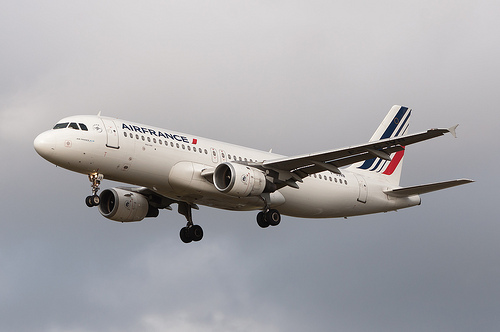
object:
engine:
[96, 187, 148, 222]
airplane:
[32, 105, 477, 243]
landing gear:
[254, 204, 283, 230]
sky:
[3, 3, 498, 98]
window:
[124, 132, 128, 137]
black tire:
[266, 209, 281, 226]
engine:
[212, 162, 266, 198]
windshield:
[53, 122, 69, 129]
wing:
[96, 188, 174, 223]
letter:
[122, 123, 131, 130]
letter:
[129, 125, 134, 132]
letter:
[141, 128, 148, 134]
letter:
[159, 131, 166, 138]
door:
[101, 118, 120, 148]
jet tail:
[344, 105, 413, 172]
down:
[82, 162, 281, 245]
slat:
[309, 160, 342, 175]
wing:
[202, 124, 458, 194]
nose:
[30, 131, 64, 158]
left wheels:
[188, 224, 204, 242]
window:
[135, 134, 139, 139]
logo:
[122, 123, 198, 145]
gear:
[175, 203, 204, 244]